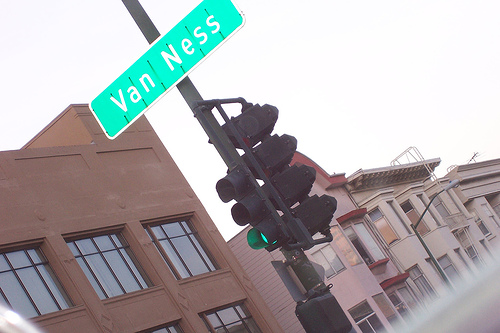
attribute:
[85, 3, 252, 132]
sign — Van Ness, street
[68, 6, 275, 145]
sign — street, Van Ness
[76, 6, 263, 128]
sign — Van Ness, street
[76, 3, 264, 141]
sign — street, Van Ness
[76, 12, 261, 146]
sign — street, Van Ness